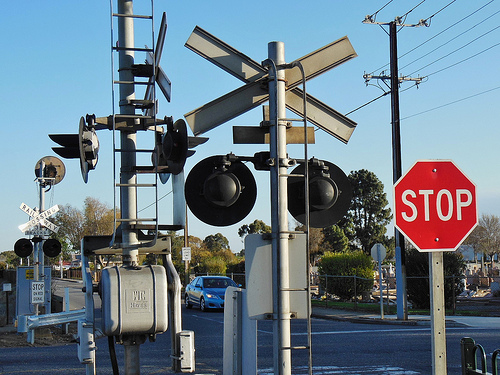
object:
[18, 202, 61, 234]
crossing sign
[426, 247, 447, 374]
metal pole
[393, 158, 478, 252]
sign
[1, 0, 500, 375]
area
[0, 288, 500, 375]
sidewalk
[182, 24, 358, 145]
sign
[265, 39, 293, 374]
pole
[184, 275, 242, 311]
car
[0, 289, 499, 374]
crossing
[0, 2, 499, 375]
railroad caution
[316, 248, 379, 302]
bush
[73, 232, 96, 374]
bar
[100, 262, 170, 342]
machine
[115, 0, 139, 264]
bar